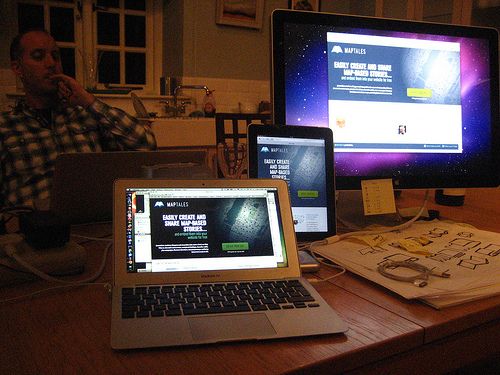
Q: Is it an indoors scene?
A: Yes, it is indoors.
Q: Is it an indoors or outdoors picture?
A: It is indoors.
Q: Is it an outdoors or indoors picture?
A: It is indoors.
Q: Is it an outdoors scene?
A: No, it is indoors.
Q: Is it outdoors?
A: No, it is indoors.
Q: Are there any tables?
A: Yes, there is a table.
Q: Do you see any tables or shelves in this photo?
A: Yes, there is a table.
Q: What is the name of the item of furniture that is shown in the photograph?
A: The piece of furniture is a table.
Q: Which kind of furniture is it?
A: The piece of furniture is a table.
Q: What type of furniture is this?
A: This is a table.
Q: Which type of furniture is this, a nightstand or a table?
A: This is a table.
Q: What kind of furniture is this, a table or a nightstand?
A: This is a table.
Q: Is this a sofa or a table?
A: This is a table.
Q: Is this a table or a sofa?
A: This is a table.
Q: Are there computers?
A: Yes, there is a computer.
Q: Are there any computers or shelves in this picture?
A: Yes, there is a computer.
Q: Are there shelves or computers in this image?
A: Yes, there is a computer.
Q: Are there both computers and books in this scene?
A: No, there is a computer but no books.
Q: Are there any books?
A: No, there are no books.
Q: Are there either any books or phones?
A: No, there are no books or phones.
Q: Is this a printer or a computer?
A: This is a computer.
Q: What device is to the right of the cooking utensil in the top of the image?
A: The device is a computer.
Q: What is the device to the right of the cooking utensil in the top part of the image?
A: The device is a computer.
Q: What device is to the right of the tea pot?
A: The device is a computer.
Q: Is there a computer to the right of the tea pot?
A: Yes, there is a computer to the right of the tea pot.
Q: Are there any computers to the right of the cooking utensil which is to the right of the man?
A: Yes, there is a computer to the right of the tea pot.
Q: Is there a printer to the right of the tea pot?
A: No, there is a computer to the right of the tea pot.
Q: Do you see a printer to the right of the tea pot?
A: No, there is a computer to the right of the tea pot.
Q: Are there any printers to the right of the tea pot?
A: No, there is a computer to the right of the tea pot.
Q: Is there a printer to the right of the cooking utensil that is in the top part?
A: No, there is a computer to the right of the tea pot.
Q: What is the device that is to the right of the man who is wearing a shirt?
A: The device is a computer.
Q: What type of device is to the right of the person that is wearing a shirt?
A: The device is a computer.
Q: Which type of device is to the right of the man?
A: The device is a computer.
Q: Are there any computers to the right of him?
A: Yes, there is a computer to the right of the man.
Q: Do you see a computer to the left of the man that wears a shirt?
A: No, the computer is to the right of the man.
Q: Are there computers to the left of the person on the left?
A: No, the computer is to the right of the man.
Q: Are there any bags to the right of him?
A: No, there is a computer to the right of the man.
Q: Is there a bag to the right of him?
A: No, there is a computer to the right of the man.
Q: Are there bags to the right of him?
A: No, there is a computer to the right of the man.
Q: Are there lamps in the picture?
A: No, there are no lamps.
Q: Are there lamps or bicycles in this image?
A: No, there are no lamps or bicycles.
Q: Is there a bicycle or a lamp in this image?
A: No, there are no lamps or bicycles.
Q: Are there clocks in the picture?
A: No, there are no clocks.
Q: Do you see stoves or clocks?
A: No, there are no clocks or stoves.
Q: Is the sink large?
A: Yes, the sink is large.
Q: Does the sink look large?
A: Yes, the sink is large.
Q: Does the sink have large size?
A: Yes, the sink is large.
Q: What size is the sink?
A: The sink is large.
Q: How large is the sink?
A: The sink is large.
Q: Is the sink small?
A: No, the sink is large.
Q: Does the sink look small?
A: No, the sink is large.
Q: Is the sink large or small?
A: The sink is large.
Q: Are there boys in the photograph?
A: No, there are no boys.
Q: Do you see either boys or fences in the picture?
A: No, there are no boys or fences.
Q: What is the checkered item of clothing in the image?
A: The clothing item is a shirt.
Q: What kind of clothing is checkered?
A: The clothing is a shirt.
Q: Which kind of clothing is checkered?
A: The clothing is a shirt.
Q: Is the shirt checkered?
A: Yes, the shirt is checkered.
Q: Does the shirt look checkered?
A: Yes, the shirt is checkered.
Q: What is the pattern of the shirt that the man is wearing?
A: The shirt is checkered.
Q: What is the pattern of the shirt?
A: The shirt is checkered.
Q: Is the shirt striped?
A: No, the shirt is checkered.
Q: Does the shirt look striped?
A: No, the shirt is checkered.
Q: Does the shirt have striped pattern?
A: No, the shirt is checkered.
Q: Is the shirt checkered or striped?
A: The shirt is checkered.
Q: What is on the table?
A: The computers are on the table.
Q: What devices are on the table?
A: The devices are computers.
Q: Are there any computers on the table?
A: Yes, there are computers on the table.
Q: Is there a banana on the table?
A: No, there are computers on the table.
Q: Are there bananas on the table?
A: No, there are computers on the table.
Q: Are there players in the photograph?
A: No, there are no players.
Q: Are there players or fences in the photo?
A: No, there are no players or fences.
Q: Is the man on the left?
A: Yes, the man is on the left of the image.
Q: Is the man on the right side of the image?
A: No, the man is on the left of the image.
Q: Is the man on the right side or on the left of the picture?
A: The man is on the left of the image.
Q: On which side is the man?
A: The man is on the left of the image.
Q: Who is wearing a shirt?
A: The man is wearing a shirt.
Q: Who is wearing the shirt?
A: The man is wearing a shirt.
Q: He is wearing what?
A: The man is wearing a shirt.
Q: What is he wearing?
A: The man is wearing a shirt.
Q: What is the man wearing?
A: The man is wearing a shirt.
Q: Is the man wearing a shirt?
A: Yes, the man is wearing a shirt.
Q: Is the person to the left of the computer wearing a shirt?
A: Yes, the man is wearing a shirt.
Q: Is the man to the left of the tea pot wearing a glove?
A: No, the man is wearing a shirt.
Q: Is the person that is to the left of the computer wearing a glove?
A: No, the man is wearing a shirt.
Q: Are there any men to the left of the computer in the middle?
A: Yes, there is a man to the left of the computer.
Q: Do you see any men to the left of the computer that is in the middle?
A: Yes, there is a man to the left of the computer.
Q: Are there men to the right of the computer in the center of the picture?
A: No, the man is to the left of the computer.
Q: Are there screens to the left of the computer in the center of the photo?
A: No, there is a man to the left of the computer.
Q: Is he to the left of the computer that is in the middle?
A: Yes, the man is to the left of the computer.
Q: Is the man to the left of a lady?
A: No, the man is to the left of the computer.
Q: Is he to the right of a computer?
A: No, the man is to the left of a computer.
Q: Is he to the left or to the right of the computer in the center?
A: The man is to the left of the computer.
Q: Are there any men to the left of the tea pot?
A: Yes, there is a man to the left of the tea pot.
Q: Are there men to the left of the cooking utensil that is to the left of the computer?
A: Yes, there is a man to the left of the tea pot.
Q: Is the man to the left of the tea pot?
A: Yes, the man is to the left of the tea pot.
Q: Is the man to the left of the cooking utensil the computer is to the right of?
A: Yes, the man is to the left of the tea pot.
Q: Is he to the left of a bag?
A: No, the man is to the left of the tea pot.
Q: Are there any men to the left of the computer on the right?
A: Yes, there is a man to the left of the computer.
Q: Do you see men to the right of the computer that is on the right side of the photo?
A: No, the man is to the left of the computer.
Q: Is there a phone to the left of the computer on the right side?
A: No, there is a man to the left of the computer.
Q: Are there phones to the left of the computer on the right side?
A: No, there is a man to the left of the computer.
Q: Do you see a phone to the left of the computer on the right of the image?
A: No, there is a man to the left of the computer.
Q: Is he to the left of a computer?
A: Yes, the man is to the left of a computer.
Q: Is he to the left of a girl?
A: No, the man is to the left of a computer.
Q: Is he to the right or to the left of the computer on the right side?
A: The man is to the left of the computer.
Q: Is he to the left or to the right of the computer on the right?
A: The man is to the left of the computer.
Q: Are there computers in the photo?
A: Yes, there is a computer.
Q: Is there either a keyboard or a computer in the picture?
A: Yes, there is a computer.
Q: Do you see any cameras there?
A: No, there are no cameras.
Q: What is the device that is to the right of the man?
A: The device is a computer.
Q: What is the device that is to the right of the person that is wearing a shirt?
A: The device is a computer.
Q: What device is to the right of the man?
A: The device is a computer.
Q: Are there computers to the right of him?
A: Yes, there is a computer to the right of the man.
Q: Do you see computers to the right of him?
A: Yes, there is a computer to the right of the man.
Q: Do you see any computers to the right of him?
A: Yes, there is a computer to the right of the man.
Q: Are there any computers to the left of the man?
A: No, the computer is to the right of the man.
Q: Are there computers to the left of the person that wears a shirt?
A: No, the computer is to the right of the man.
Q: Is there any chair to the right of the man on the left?
A: No, there is a computer to the right of the man.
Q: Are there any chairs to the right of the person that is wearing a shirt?
A: No, there is a computer to the right of the man.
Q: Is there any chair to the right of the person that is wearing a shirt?
A: No, there is a computer to the right of the man.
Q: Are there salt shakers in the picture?
A: No, there are no salt shakers.